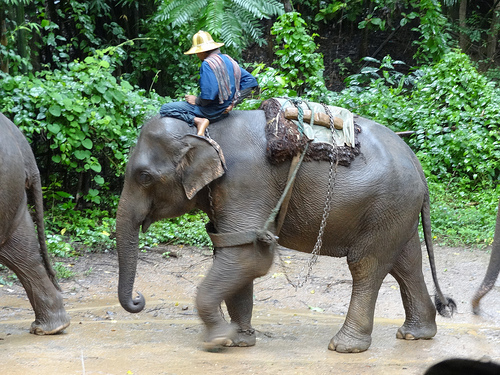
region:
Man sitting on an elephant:
[136, 26, 276, 153]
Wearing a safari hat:
[161, 16, 256, 83]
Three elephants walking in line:
[2, 20, 498, 345]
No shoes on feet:
[172, 108, 231, 150]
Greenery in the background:
[8, 2, 205, 85]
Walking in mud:
[78, 263, 373, 374]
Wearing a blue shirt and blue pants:
[166, 10, 263, 147]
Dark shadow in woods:
[293, 5, 481, 105]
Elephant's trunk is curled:
[105, 248, 155, 330]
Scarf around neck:
[185, 28, 255, 110]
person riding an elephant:
[166, 26, 256, 137]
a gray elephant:
[116, 116, 452, 336]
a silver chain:
[280, 136, 346, 286]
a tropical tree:
[153, 1, 348, 32]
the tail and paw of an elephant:
[3, 116, 93, 336]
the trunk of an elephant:
[472, 195, 497, 330]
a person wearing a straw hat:
[171, 20, 223, 55]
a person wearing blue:
[190, 51, 255, 106]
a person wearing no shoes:
[180, 110, 225, 145]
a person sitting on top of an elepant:
[131, 24, 463, 329]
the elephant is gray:
[92, 103, 445, 347]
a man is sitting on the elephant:
[159, 20, 270, 142]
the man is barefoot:
[189, 103, 215, 143]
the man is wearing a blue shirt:
[192, 52, 264, 113]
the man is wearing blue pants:
[145, 100, 223, 140]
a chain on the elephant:
[311, 100, 342, 285]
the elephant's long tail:
[407, 147, 460, 321]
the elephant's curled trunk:
[110, 182, 148, 312]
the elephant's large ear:
[160, 131, 231, 202]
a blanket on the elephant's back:
[253, 94, 357, 175]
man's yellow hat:
[185, 22, 225, 57]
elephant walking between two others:
[108, 77, 444, 357]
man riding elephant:
[162, 20, 258, 135]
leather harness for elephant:
[200, 147, 312, 269]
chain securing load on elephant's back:
[300, 97, 346, 285]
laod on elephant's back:
[260, 96, 369, 166]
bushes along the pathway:
[1, 77, 493, 242]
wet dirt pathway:
[17, 248, 495, 360]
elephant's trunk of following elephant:
[473, 176, 498, 325]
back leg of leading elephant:
[6, 120, 78, 361]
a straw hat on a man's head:
[186, 30, 225, 55]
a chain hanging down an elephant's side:
[313, 167, 335, 260]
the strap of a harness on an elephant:
[211, 225, 273, 251]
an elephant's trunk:
[113, 223, 147, 312]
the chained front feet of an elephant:
[198, 310, 262, 355]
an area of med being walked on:
[96, 317, 181, 374]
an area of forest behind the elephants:
[373, 35, 494, 117]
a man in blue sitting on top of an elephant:
[156, 41, 250, 123]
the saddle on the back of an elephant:
[271, 94, 367, 164]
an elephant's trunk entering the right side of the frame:
[467, 207, 498, 316]